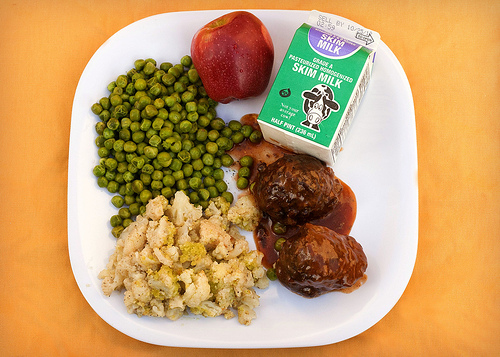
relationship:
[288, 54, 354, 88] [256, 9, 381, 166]
letters on top of carton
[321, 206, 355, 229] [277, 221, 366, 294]
sauce on top of meatball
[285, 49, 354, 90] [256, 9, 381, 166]
letters on top of carton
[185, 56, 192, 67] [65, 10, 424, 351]
pea on top of plate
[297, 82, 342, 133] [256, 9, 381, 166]
cow on top of carton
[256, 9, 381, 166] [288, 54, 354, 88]
carton has letters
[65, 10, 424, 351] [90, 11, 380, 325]
plate of food